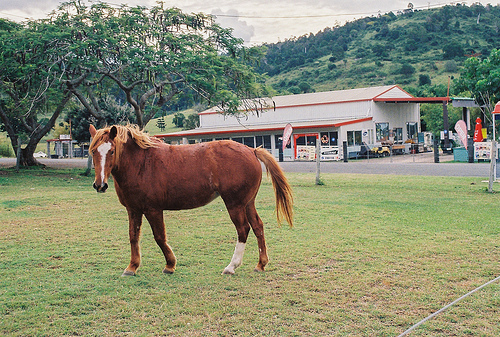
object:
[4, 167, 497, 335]
grass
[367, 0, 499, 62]
skies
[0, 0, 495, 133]
hills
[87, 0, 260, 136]
trees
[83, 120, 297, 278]
brown horse